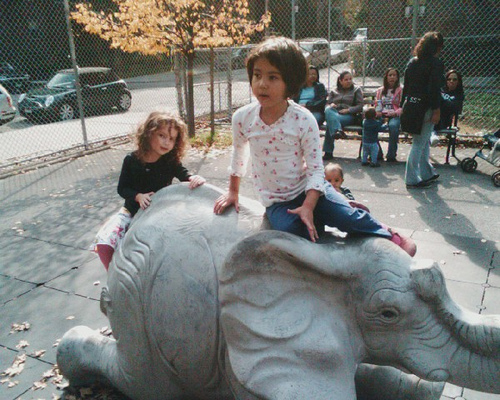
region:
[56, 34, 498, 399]
Two children on an elephant statue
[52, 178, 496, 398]
Grey elephant statue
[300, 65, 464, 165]
Four women sitting on a bench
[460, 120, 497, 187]
Front part of a stroller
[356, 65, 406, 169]
Small toddler standing in front of a woman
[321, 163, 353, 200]
Toddler hidden behind a girl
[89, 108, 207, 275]
Young girl climbing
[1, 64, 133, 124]
Two cars parked on the side of a road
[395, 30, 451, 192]
Woman standing up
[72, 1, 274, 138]
Tree with autumn leaves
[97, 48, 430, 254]
girls playing on elephant statute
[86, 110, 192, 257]
girl wearing black shirt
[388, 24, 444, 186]
woman with black bag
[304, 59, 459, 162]
four women sitting on bench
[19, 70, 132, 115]
car driving down road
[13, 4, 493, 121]
fence around the playground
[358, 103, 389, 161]
child standing by bench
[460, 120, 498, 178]
stroller beside the bench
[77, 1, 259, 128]
tree with yellow leaves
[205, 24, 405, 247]
girl sitting on top of elephant statute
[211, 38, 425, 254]
child with white shirt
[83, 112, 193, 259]
child climbing onto elephant statute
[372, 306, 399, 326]
eye of elephant statute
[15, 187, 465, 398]
leaves scattered on playground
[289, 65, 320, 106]
woman wearing blue shirt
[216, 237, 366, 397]
ear of elephant statute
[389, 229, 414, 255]
pink shoelaces on girl's shoe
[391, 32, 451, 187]
woman standing in front of bench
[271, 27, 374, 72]
cars parked on street in background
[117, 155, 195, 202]
black shirt of girl climbing on elephant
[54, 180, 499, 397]
A stone statue of an elephant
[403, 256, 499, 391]
Stone elephant with its trunk up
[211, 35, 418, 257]
A girl sitting on the elephant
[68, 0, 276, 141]
A tree with orange leaves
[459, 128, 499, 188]
Part of a stroller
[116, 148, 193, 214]
A girl in a black shirt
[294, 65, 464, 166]
Women sitting on a bench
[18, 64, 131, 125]
A dark car parked on the street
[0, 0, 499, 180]
A chain link fence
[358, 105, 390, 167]
A child wearing blue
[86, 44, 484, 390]
Fall day local park.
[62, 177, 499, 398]
Concrete scuplture fun elephant.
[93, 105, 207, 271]
Not sure she can climb on top.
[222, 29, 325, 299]
Older sister sits atop elephant.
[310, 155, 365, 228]
Little one looks on sisters.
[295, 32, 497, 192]
Mothers sit bench watch children.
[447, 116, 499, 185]
Baby stroller wheels showing.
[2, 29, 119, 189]
Chainlink fence surrounds park.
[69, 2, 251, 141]
Leaves still tree ready fall.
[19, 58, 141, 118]
Small car moving in traffic.